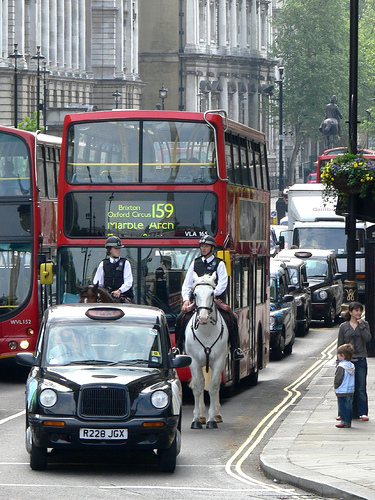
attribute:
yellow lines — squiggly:
[222, 334, 346, 496]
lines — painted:
[222, 432, 257, 484]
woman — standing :
[336, 299, 372, 422]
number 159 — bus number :
[150, 200, 174, 219]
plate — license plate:
[76, 426, 133, 443]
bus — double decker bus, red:
[58, 100, 276, 424]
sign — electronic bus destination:
[105, 200, 176, 233]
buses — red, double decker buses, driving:
[3, 102, 274, 399]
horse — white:
[181, 270, 232, 429]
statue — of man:
[310, 103, 351, 146]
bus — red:
[56, 108, 273, 399]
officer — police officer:
[176, 228, 238, 331]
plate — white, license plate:
[77, 425, 127, 441]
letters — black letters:
[82, 428, 124, 437]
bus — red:
[35, 72, 283, 348]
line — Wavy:
[222, 311, 372, 499]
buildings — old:
[31, 1, 246, 88]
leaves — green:
[257, 3, 373, 154]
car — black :
[15, 253, 207, 494]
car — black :
[25, 278, 180, 479]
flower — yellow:
[351, 161, 357, 169]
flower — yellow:
[357, 158, 364, 166]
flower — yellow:
[329, 175, 335, 183]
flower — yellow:
[364, 173, 371, 181]